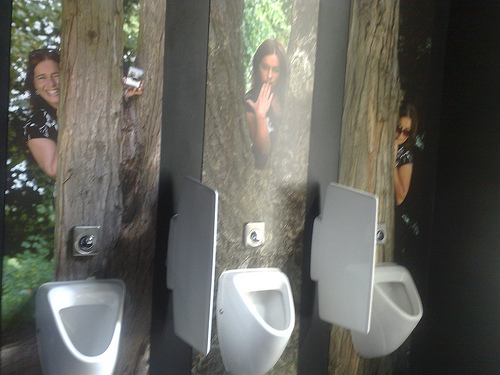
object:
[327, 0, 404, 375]
tree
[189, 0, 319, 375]
tree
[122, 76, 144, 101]
hand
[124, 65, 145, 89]
picture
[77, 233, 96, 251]
push button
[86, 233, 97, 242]
silver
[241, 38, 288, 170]
person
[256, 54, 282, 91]
surprised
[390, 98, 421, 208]
woman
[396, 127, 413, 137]
sunglasses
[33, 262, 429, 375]
three urinals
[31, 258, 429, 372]
row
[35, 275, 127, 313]
top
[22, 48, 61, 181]
person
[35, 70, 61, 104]
smiling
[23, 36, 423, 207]
three women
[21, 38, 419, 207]
row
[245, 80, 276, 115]
hand on her mouth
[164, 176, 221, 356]
urinal divider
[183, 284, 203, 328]
white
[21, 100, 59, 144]
black dress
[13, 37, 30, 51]
plants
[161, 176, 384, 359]
two dividers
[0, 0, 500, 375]
bathroom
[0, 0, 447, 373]
wall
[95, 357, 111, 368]
white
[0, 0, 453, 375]
picture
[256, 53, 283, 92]
laughing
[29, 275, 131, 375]
urinal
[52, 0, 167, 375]
tree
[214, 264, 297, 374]
urinal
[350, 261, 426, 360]
urinal